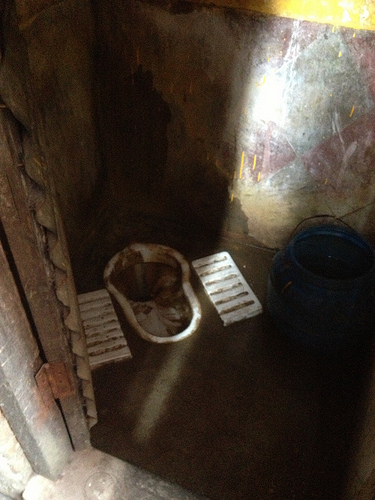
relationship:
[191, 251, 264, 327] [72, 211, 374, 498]
floor on floor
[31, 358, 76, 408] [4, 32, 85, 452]
hinge on door